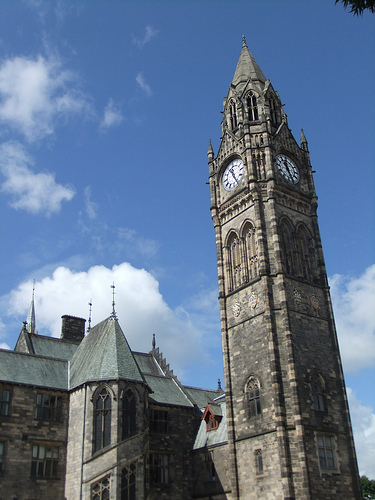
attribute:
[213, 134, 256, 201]
clock — large, tower, white, grey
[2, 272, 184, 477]
church — large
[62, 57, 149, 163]
sky — blue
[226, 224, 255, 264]
window — framed, glass, arched, wood, grey, dark, narrow, flower, tower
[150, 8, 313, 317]
tower — point, clock, pointed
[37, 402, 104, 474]
stone — grey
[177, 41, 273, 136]
top — green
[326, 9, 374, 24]
tree — limb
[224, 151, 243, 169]
twelve — roman numeral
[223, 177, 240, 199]
six — roman numeral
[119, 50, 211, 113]
cloud — puff